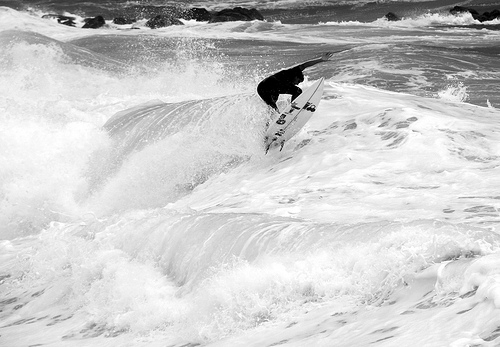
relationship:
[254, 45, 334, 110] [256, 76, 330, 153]
man on surfboard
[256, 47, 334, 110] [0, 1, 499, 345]
man in water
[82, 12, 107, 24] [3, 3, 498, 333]
rock in ocean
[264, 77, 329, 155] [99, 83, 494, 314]
surfboard on wave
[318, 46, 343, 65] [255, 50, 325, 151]
hand of surfer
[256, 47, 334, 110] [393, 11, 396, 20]
man in air